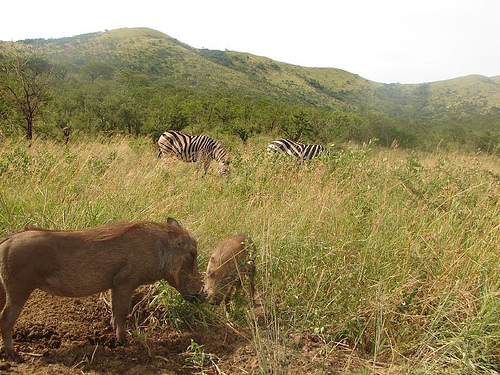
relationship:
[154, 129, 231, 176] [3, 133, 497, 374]
zebras are in grass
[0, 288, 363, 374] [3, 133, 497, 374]
dirt amidst grass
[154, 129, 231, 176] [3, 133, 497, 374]
zebras are hidden by grass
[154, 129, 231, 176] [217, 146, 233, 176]
zebras have head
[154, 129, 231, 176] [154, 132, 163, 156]
zebras have tail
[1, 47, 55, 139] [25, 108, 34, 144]
trees have trunk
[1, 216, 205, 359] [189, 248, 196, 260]
animals have eye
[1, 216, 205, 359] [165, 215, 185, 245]
animals have ear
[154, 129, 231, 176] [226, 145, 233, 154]
zebras have ears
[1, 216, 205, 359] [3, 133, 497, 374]
animals are in grass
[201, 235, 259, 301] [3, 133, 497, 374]
pig in grass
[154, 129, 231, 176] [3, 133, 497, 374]
zebras are grazing in grass